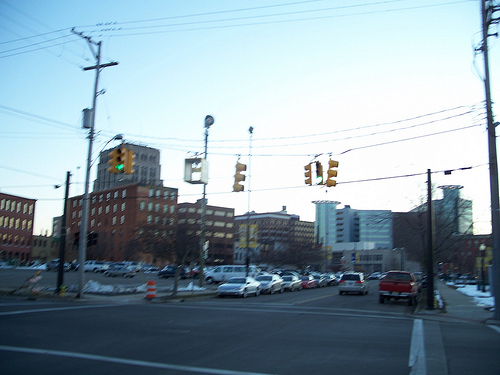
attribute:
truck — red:
[375, 266, 417, 308]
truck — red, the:
[379, 270, 424, 307]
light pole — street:
[195, 110, 216, 290]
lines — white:
[173, 295, 499, 328]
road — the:
[160, 311, 322, 368]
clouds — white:
[225, 44, 387, 136]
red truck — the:
[377, 271, 422, 303]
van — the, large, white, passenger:
[206, 262, 258, 284]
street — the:
[0, 273, 492, 370]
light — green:
[108, 147, 133, 175]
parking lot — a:
[0, 261, 315, 298]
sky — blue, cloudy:
[254, 47, 390, 113]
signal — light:
[207, 154, 259, 194]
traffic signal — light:
[228, 152, 251, 195]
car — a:
[336, 265, 369, 295]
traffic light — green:
[101, 136, 153, 188]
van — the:
[213, 266, 278, 284]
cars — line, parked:
[215, 267, 333, 302]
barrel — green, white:
[146, 278, 158, 300]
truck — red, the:
[336, 251, 448, 311]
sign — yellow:
[228, 219, 278, 260]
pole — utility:
[70, 25, 118, 300]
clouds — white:
[243, 85, 447, 170]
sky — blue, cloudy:
[1, 2, 498, 248]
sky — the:
[145, 43, 365, 125]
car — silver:
[335, 270, 370, 298]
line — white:
[168, 294, 424, 313]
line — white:
[139, 299, 413, 319]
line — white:
[3, 341, 231, 374]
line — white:
[403, 313, 423, 371]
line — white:
[0, 299, 126, 316]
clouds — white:
[12, 98, 80, 155]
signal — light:
[326, 155, 339, 189]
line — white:
[237, 300, 392, 317]